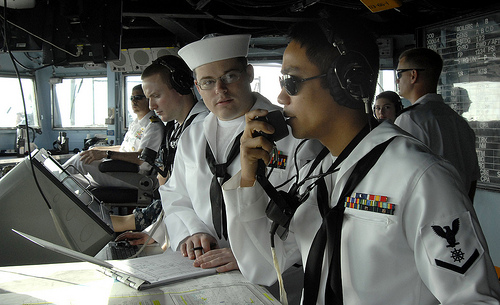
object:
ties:
[204, 127, 405, 304]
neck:
[319, 107, 379, 157]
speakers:
[106, 46, 183, 73]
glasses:
[193, 67, 252, 90]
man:
[395, 47, 483, 205]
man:
[375, 91, 406, 124]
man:
[157, 31, 323, 274]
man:
[110, 54, 209, 254]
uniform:
[221, 126, 500, 303]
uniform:
[393, 93, 481, 203]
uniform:
[120, 110, 167, 171]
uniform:
[160, 99, 209, 176]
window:
[53, 75, 115, 129]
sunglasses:
[277, 71, 334, 96]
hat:
[178, 32, 252, 72]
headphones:
[324, 22, 376, 99]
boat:
[0, 0, 499, 302]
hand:
[234, 109, 277, 185]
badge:
[342, 192, 398, 214]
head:
[275, 15, 382, 141]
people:
[78, 12, 500, 305]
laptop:
[10, 228, 220, 290]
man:
[79, 84, 166, 173]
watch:
[106, 150, 113, 159]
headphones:
[152, 58, 196, 94]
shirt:
[220, 121, 499, 303]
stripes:
[340, 192, 396, 215]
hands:
[176, 231, 241, 273]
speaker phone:
[249, 109, 299, 226]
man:
[220, 14, 499, 304]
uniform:
[158, 91, 307, 297]